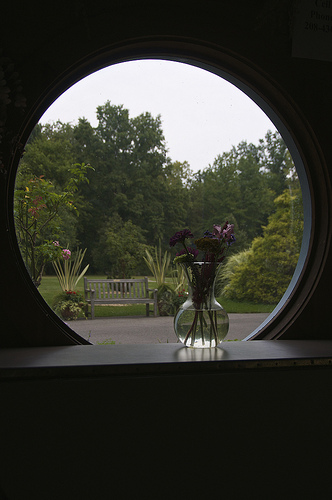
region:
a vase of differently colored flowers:
[171, 218, 238, 347]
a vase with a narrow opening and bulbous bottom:
[177, 262, 233, 346]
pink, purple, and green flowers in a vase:
[171, 222, 242, 279]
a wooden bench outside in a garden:
[80, 275, 161, 312]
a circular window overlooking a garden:
[6, 33, 330, 340]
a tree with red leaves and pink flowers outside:
[9, 168, 82, 296]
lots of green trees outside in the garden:
[13, 97, 287, 304]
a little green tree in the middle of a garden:
[95, 220, 147, 298]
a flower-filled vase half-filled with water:
[162, 222, 244, 349]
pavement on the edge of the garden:
[67, 310, 265, 339]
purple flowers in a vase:
[168, 221, 233, 346]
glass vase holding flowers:
[169, 221, 236, 349]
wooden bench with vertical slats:
[83, 276, 160, 318]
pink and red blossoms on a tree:
[13, 172, 72, 289]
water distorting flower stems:
[173, 301, 230, 348]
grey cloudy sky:
[21, 58, 298, 177]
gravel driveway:
[53, 311, 271, 341]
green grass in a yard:
[32, 274, 286, 312]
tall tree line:
[35, 122, 287, 273]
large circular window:
[6, 36, 330, 343]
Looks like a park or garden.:
[39, 126, 189, 314]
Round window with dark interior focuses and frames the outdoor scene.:
[15, 27, 326, 415]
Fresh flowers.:
[152, 212, 251, 369]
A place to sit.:
[75, 269, 167, 326]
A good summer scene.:
[35, 147, 167, 296]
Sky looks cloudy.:
[51, 90, 225, 148]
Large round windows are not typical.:
[9, 46, 325, 352]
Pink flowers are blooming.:
[32, 217, 97, 269]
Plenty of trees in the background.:
[43, 130, 264, 221]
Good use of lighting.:
[14, 168, 320, 407]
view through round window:
[9, 46, 324, 367]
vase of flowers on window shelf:
[164, 210, 249, 352]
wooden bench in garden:
[80, 271, 166, 322]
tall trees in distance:
[29, 152, 288, 285]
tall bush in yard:
[96, 211, 161, 295]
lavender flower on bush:
[43, 231, 78, 281]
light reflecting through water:
[165, 314, 237, 368]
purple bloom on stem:
[167, 224, 194, 259]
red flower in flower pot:
[55, 285, 91, 312]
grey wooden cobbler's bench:
[79, 271, 166, 323]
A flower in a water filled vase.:
[163, 216, 264, 364]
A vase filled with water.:
[153, 258, 258, 363]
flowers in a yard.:
[37, 230, 103, 322]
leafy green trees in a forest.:
[86, 98, 181, 285]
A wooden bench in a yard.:
[73, 262, 158, 322]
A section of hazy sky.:
[182, 89, 230, 127]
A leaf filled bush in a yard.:
[218, 223, 302, 321]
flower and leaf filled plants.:
[13, 170, 87, 280]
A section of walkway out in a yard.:
[103, 269, 153, 298]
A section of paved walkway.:
[87, 320, 153, 351]